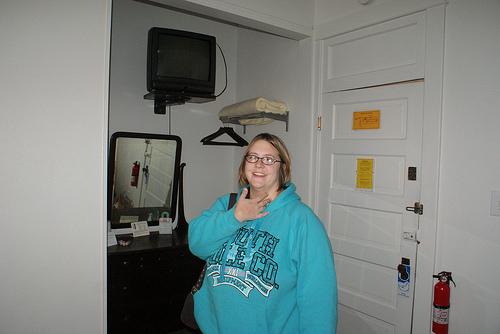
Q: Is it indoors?
A: Yes, it is indoors.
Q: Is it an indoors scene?
A: Yes, it is indoors.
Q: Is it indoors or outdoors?
A: It is indoors.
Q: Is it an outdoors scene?
A: No, it is indoors.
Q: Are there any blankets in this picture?
A: Yes, there is a blanket.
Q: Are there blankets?
A: Yes, there is a blanket.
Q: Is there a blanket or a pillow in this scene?
A: Yes, there is a blanket.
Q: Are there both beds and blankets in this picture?
A: No, there is a blanket but no beds.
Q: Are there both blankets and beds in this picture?
A: No, there is a blanket but no beds.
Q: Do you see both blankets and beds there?
A: No, there is a blanket but no beds.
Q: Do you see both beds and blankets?
A: No, there is a blanket but no beds.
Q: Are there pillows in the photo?
A: No, there are no pillows.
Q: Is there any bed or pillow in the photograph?
A: No, there are no pillows or beds.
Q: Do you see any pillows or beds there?
A: No, there are no pillows or beds.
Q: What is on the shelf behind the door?
A: The blanket is on the shelf.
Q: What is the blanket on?
A: The blanket is on the shelf.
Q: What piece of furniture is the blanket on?
A: The blanket is on the shelf.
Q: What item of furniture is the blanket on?
A: The blanket is on the shelf.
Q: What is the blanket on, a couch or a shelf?
A: The blanket is on a shelf.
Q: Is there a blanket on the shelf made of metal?
A: Yes, there is a blanket on the shelf.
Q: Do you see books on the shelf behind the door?
A: No, there is a blanket on the shelf.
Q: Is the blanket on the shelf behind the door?
A: Yes, the blanket is on the shelf.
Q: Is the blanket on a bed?
A: No, the blanket is on the shelf.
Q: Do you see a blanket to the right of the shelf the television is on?
A: Yes, there is a blanket to the right of the shelf.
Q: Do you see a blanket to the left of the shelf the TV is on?
A: No, the blanket is to the right of the shelf.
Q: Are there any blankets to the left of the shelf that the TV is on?
A: No, the blanket is to the right of the shelf.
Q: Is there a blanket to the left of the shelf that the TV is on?
A: No, the blanket is to the right of the shelf.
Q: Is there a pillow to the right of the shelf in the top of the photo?
A: No, there is a blanket to the right of the shelf.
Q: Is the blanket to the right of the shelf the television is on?
A: Yes, the blanket is to the right of the shelf.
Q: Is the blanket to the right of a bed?
A: No, the blanket is to the right of the shelf.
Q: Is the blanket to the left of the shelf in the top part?
A: No, the blanket is to the right of the shelf.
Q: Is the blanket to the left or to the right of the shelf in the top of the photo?
A: The blanket is to the right of the shelf.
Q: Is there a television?
A: Yes, there is a television.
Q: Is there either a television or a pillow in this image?
A: Yes, there is a television.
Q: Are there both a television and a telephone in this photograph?
A: No, there is a television but no phones.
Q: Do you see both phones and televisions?
A: No, there is a television but no phones.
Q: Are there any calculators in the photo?
A: No, there are no calculators.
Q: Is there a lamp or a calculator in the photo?
A: No, there are no calculators or lamps.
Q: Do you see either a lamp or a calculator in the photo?
A: No, there are no calculators or lamps.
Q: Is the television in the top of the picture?
A: Yes, the television is in the top of the image.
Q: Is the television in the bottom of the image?
A: No, the television is in the top of the image.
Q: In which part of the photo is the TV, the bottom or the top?
A: The TV is in the top of the image.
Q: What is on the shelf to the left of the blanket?
A: The television is on the shelf.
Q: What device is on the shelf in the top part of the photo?
A: The device is a television.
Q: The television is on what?
A: The television is on the shelf.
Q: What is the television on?
A: The television is on the shelf.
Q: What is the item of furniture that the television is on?
A: The piece of furniture is a shelf.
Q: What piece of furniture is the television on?
A: The television is on the shelf.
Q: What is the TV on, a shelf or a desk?
A: The TV is on a shelf.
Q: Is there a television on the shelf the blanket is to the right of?
A: Yes, there is a television on the shelf.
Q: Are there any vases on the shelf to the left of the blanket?
A: No, there is a television on the shelf.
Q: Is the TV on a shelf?
A: Yes, the TV is on a shelf.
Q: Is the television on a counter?
A: No, the television is on a shelf.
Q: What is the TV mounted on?
A: The TV is mounted on the wall.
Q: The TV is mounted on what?
A: The TV is mounted on the wall.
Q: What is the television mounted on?
A: The TV is mounted on the wall.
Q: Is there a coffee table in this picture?
A: No, there are no coffee tables.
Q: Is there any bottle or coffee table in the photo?
A: No, there are no coffee tables or bottles.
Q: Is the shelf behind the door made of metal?
A: Yes, the shelf is made of metal.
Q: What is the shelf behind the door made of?
A: The shelf is made of metal.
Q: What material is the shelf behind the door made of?
A: The shelf is made of metal.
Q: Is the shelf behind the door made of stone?
A: No, the shelf is made of metal.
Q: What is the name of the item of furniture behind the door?
A: The piece of furniture is a shelf.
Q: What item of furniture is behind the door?
A: The piece of furniture is a shelf.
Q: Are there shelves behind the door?
A: Yes, there is a shelf behind the door.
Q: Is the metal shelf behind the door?
A: Yes, the shelf is behind the door.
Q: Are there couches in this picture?
A: No, there are no couches.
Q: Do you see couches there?
A: No, there are no couches.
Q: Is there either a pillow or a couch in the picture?
A: No, there are no couches or pillows.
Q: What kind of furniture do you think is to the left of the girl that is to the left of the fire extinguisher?
A: The piece of furniture is a dresser.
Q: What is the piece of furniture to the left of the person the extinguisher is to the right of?
A: The piece of furniture is a dresser.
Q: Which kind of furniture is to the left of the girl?
A: The piece of furniture is a dresser.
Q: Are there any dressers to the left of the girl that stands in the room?
A: Yes, there is a dresser to the left of the girl.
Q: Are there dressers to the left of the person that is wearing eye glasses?
A: Yes, there is a dresser to the left of the girl.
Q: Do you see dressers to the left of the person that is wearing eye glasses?
A: Yes, there is a dresser to the left of the girl.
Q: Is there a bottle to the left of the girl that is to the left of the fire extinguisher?
A: No, there is a dresser to the left of the girl.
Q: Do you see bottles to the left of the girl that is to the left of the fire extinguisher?
A: No, there is a dresser to the left of the girl.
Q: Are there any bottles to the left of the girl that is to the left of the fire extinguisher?
A: No, there is a dresser to the left of the girl.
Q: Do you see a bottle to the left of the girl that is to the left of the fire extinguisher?
A: No, there is a dresser to the left of the girl.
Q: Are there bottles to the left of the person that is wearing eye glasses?
A: No, there is a dresser to the left of the girl.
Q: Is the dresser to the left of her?
A: Yes, the dresser is to the left of the girl.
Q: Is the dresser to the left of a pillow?
A: No, the dresser is to the left of the girl.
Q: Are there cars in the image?
A: No, there are no cars.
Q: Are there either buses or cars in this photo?
A: No, there are no cars or buses.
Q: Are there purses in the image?
A: Yes, there is a purse.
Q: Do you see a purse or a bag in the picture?
A: Yes, there is a purse.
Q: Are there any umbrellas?
A: No, there are no umbrellas.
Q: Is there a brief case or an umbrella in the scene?
A: No, there are no umbrellas or briefcases.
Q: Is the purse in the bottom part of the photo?
A: Yes, the purse is in the bottom of the image.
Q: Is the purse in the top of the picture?
A: No, the purse is in the bottom of the image.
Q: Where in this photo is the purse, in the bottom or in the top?
A: The purse is in the bottom of the image.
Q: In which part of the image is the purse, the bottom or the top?
A: The purse is in the bottom of the image.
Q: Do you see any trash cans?
A: No, there are no trash cans.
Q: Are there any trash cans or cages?
A: No, there are no trash cans or cages.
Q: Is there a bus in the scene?
A: No, there are no buses.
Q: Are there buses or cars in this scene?
A: No, there are no buses or cars.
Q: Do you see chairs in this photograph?
A: No, there are no chairs.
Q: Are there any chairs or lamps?
A: No, there are no chairs or lamps.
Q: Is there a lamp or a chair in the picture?
A: No, there are no chairs or lamps.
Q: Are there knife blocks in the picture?
A: No, there are no knife blocks.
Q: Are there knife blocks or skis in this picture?
A: No, there are no knife blocks or skis.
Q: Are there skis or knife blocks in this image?
A: No, there are no knife blocks or skis.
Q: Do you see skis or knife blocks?
A: No, there are no knife blocks or skis.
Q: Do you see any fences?
A: No, there are no fences.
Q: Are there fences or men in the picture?
A: No, there are no fences or men.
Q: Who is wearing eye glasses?
A: The girl is wearing eye glasses.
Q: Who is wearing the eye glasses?
A: The girl is wearing eye glasses.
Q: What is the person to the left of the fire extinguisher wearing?
A: The girl is wearing eye glasses.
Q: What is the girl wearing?
A: The girl is wearing eye glasses.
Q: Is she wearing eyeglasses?
A: Yes, the girl is wearing eyeglasses.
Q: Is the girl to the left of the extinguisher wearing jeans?
A: No, the girl is wearing eyeglasses.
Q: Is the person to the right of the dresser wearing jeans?
A: No, the girl is wearing eyeglasses.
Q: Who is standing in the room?
A: The girl is standing in the room.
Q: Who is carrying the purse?
A: The girl is carrying the purse.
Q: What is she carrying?
A: The girl is carrying a purse.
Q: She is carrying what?
A: The girl is carrying a purse.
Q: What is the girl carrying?
A: The girl is carrying a purse.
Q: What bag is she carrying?
A: The girl is carrying a purse.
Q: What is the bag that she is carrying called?
A: The bag is a purse.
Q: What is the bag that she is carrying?
A: The bag is a purse.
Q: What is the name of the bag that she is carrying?
A: The bag is a purse.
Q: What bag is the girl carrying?
A: The girl is carrying a purse.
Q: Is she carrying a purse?
A: Yes, the girl is carrying a purse.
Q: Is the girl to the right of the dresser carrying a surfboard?
A: No, the girl is carrying a purse.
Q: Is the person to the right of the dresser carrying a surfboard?
A: No, the girl is carrying a purse.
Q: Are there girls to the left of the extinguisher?
A: Yes, there is a girl to the left of the extinguisher.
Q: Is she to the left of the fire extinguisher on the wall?
A: Yes, the girl is to the left of the fire extinguisher.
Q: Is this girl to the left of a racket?
A: No, the girl is to the left of the fire extinguisher.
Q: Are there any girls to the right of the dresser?
A: Yes, there is a girl to the right of the dresser.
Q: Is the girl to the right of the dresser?
A: Yes, the girl is to the right of the dresser.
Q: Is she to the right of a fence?
A: No, the girl is to the right of the dresser.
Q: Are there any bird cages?
A: No, there are no bird cages.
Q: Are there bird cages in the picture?
A: No, there are no bird cages.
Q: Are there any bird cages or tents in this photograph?
A: No, there are no bird cages or tents.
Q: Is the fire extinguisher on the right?
A: Yes, the fire extinguisher is on the right of the image.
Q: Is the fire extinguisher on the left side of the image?
A: No, the fire extinguisher is on the right of the image.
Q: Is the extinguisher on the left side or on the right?
A: The extinguisher is on the right of the image.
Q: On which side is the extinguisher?
A: The extinguisher is on the right of the image.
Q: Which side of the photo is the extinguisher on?
A: The extinguisher is on the right of the image.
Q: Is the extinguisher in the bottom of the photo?
A: Yes, the extinguisher is in the bottom of the image.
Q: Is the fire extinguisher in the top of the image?
A: No, the fire extinguisher is in the bottom of the image.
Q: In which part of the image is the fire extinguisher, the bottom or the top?
A: The fire extinguisher is in the bottom of the image.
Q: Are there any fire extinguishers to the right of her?
A: Yes, there is a fire extinguisher to the right of the girl.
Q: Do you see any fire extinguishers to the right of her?
A: Yes, there is a fire extinguisher to the right of the girl.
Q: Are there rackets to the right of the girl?
A: No, there is a fire extinguisher to the right of the girl.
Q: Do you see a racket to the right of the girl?
A: No, there is a fire extinguisher to the right of the girl.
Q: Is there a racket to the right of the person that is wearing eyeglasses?
A: No, there is a fire extinguisher to the right of the girl.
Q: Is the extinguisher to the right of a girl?
A: Yes, the extinguisher is to the right of a girl.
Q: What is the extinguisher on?
A: The extinguisher is on the wall.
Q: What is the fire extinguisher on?
A: The extinguisher is on the wall.